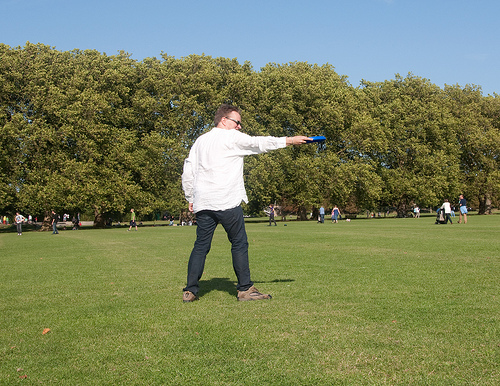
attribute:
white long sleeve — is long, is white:
[178, 125, 285, 210]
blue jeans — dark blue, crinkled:
[178, 198, 262, 291]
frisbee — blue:
[302, 132, 327, 145]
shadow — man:
[190, 261, 293, 299]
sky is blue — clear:
[0, 1, 497, 95]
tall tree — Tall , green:
[20, 44, 97, 231]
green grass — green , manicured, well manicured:
[1, 209, 499, 385]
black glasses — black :
[228, 114, 243, 128]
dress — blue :
[330, 204, 342, 224]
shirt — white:
[168, 120, 292, 225]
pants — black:
[180, 200, 254, 297]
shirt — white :
[178, 122, 294, 223]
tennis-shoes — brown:
[179, 285, 270, 305]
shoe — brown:
[179, 286, 273, 303]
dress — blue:
[336, 209, 338, 218]